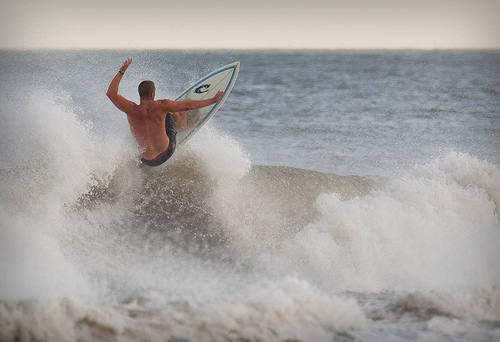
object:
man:
[108, 56, 228, 170]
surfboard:
[165, 64, 243, 150]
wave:
[294, 151, 500, 312]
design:
[193, 101, 213, 112]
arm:
[106, 59, 136, 111]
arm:
[106, 58, 224, 114]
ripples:
[0, 49, 500, 163]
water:
[0, 46, 499, 341]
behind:
[138, 136, 171, 162]